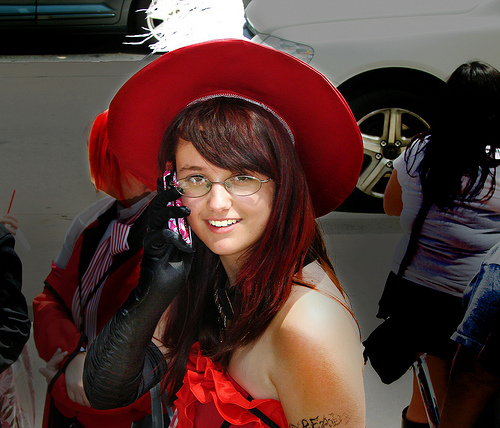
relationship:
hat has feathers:
[73, 30, 376, 244] [134, 0, 296, 85]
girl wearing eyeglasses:
[164, 158, 343, 311] [158, 165, 312, 229]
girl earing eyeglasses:
[164, 158, 343, 311] [158, 165, 312, 229]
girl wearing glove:
[164, 158, 343, 311] [62, 198, 187, 400]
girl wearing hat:
[164, 158, 343, 311] [73, 30, 376, 244]